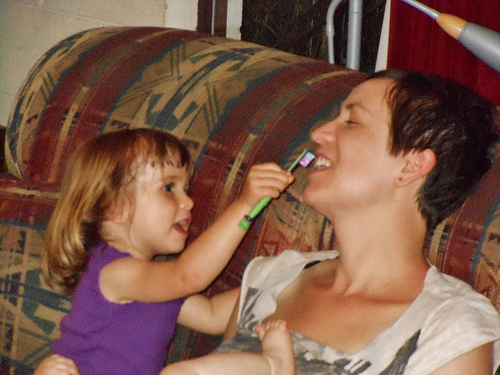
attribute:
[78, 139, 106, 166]
hair — long, messy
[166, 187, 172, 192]
eye — open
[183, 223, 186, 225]
teeth — white, straight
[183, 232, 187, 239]
lip — pink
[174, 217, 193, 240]
mouth — open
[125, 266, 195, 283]
arm — extended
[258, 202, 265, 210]
handle — green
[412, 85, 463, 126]
hair — short, dark, black